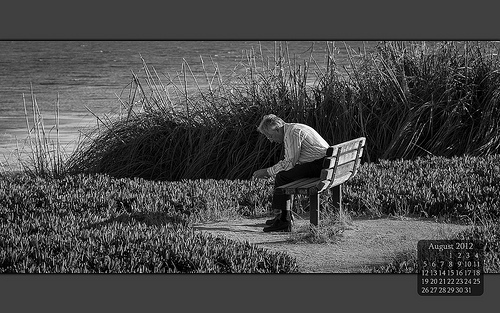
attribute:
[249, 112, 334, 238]
man — older, sitting, elderly, leaning, looking down, looking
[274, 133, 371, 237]
park bench — wooden, wood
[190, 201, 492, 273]
platform — small, concrete, square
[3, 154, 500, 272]
grass — medium length, cut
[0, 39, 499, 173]
water — calm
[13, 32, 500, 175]
grass — long, green, tall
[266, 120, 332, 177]
shirt — striped, long sleeved, button down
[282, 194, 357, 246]
grass — overgrown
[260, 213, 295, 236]
shoes — dark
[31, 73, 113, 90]
ripples — small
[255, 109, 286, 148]
head — angled, down